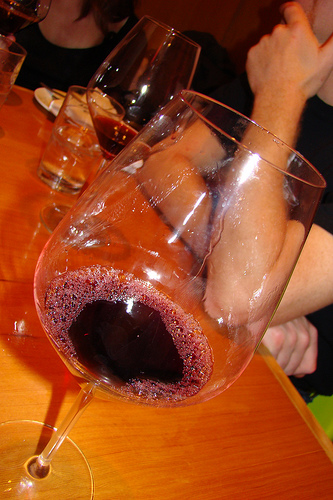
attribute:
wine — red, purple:
[41, 247, 240, 410]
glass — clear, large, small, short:
[20, 79, 330, 350]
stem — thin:
[16, 355, 134, 478]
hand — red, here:
[233, 15, 325, 102]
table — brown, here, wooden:
[23, 96, 264, 471]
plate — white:
[30, 75, 117, 138]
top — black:
[13, 10, 115, 112]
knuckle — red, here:
[243, 23, 293, 64]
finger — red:
[271, 4, 319, 27]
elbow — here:
[191, 234, 256, 347]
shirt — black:
[206, 81, 320, 292]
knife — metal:
[25, 74, 84, 114]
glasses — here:
[24, 30, 331, 497]